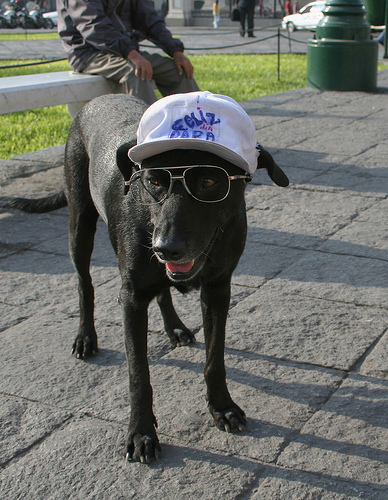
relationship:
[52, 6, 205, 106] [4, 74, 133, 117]
man sitting on bench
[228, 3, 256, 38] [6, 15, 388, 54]
person crossing street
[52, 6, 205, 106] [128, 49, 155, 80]
man has hand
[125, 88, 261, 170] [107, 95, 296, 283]
cap on head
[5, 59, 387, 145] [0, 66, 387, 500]
grass next to sidewalk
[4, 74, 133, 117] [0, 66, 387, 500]
bench at end of sidewalk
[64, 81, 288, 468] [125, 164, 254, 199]
dog has glasses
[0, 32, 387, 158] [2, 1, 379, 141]
grass in background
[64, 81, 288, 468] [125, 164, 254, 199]
dog wearing glasses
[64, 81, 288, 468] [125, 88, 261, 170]
dog wearing cap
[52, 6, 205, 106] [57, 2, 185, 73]
man wearing jacket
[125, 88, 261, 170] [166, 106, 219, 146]
cap has letters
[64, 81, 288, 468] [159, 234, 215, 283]
dog has a mouth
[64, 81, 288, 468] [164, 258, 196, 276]
dog has tongue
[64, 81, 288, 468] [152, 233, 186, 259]
dog has nose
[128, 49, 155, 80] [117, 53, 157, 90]
hand on knee